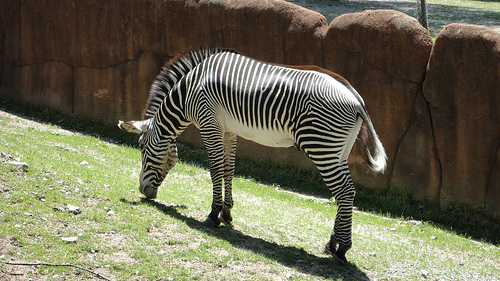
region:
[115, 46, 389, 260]
lone zebra is grazing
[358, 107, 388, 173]
tail on zebra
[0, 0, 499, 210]
brown stone wall behind zebra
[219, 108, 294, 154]
zebra belly is white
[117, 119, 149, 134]
ear on zebra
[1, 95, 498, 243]
dark shadow beside wall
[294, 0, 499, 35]
metal fence behind wall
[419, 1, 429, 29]
fence post behind wall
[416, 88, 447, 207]
crack on stone wall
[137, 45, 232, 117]
black and white zebra mane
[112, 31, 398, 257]
zebra standing in an enclosure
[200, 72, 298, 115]
stripes on zebra's back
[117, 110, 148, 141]
ear on the zebra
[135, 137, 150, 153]
eye on the zebra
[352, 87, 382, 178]
tail on the zebra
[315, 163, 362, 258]
back legs of the zebra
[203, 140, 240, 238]
front legs of the zebra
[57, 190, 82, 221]
rock on the ground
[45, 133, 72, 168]
grass on the ground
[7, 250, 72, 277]
stick on the ground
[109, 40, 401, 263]
a zebra grazing on grass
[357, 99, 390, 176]
the tail of a zebra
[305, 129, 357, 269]
the hind leg of a zebra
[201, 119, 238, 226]
the front leg of a zebra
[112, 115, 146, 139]
the ear of a zebra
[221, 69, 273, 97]
the stripes of a zebra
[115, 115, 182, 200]
the head of a zebra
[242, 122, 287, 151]
the stomach of a zebra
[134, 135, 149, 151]
the eye of a zebra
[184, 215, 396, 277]
the shadow of a zebra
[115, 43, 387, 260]
black and white zebra eating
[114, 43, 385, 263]
zebra eating grass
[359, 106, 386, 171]
fuzzy zebra tail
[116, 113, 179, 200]
zebra downward facing head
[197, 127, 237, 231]
front legs of zebra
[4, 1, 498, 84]
false boulder retaining wall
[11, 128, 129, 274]
patchy grass feed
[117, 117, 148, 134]
left ear of a zebra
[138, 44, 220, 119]
zebra mane standing straight up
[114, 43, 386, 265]
zebra standing on an incline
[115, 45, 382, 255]
a zebra eating some grass on the ground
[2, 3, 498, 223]
a stone wall next to the zebra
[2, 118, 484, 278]
the grass sitting on the ground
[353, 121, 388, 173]
the tail of the zebra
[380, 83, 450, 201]
the cracks in the wall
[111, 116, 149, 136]
the big ears of the zebra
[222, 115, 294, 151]
the white belly of the zebra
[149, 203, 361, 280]
the shadow of the zebra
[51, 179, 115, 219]
little stones on the ground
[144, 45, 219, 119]
the mane of the zebra